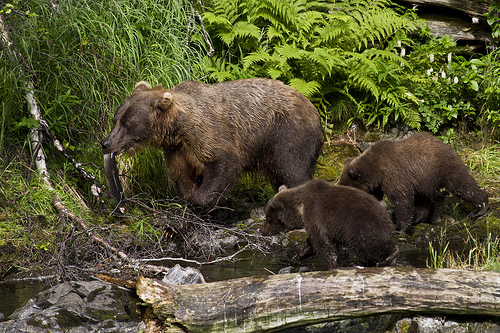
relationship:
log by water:
[117, 260, 499, 329] [9, 276, 44, 328]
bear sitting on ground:
[258, 179, 398, 279] [4, 173, 493, 325]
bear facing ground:
[99, 77, 326, 222] [146, 200, 276, 288]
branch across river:
[31, 162, 192, 331] [205, 257, 265, 284]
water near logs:
[4, 278, 37, 303] [84, 267, 498, 314]